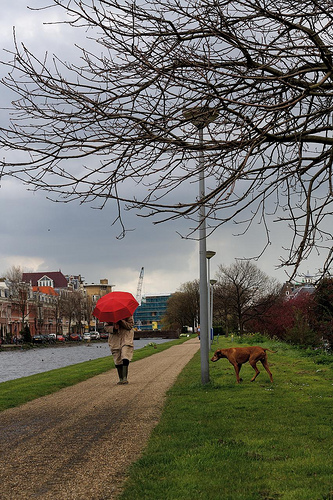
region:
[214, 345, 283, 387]
dog on the grass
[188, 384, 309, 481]
green grass alongside the sidewalk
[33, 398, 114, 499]
pathway the man is walking on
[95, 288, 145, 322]
red umbrella top that the man is carrying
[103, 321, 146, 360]
trenchcoat on the man walking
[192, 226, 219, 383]
light pole on the grass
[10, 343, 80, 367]
Water in the river next to the path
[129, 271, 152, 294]
building crane downtown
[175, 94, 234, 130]
light on a pole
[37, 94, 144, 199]
tree branches with no leaves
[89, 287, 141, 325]
red umbrella in rain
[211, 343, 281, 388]
brown dog walking across grass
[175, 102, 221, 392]
tall street light on metal pole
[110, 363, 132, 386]
pair of black rubber rain boots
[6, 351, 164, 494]
long tan sidewalk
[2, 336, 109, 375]
narrow body of water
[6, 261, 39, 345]
tall leafless trees bordering long narrow body of water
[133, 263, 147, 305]
tall construction ladder in horizon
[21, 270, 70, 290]
red rooftop on building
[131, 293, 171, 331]
multi-story blue building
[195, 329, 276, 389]
brown dog sniffing light post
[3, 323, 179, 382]
river with buildings on one bank and a walkway on the other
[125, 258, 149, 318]
industrial crane extended into the air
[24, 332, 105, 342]
vehicles parked along a row of store fronts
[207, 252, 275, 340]
tree with no leaves on it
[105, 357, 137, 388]
tall rubber boots for water protection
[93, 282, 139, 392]
person in tan coat holding a red umbrella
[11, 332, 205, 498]
walkway along river bank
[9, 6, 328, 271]
overcast sky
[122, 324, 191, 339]
bridge over a river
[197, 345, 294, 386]
brown dog running on grass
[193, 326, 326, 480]
green patch of medium length grass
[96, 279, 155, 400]
man in raincoat on sidewalk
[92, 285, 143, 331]
bright red umbrella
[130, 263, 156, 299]
Tall construction crane in background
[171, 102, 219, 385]
Tall grey light pole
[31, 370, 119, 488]
brown gravel side walk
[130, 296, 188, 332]
blue building under contruction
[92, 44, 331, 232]
Leave-less branches of tree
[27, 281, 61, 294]
orange rooftop of building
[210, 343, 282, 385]
Brown dog on grass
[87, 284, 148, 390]
Person walking on dirt road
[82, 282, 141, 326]
Red umbrella being carried by a person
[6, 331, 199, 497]
Dirt road being walked on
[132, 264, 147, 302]
A crane in the distance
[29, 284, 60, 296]
Orange roof of a building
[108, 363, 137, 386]
Galoshes of a person walking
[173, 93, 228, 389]
3 lamp posts along a dirt road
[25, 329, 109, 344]
A line of parked cars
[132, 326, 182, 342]
Stone bridge over a waterway